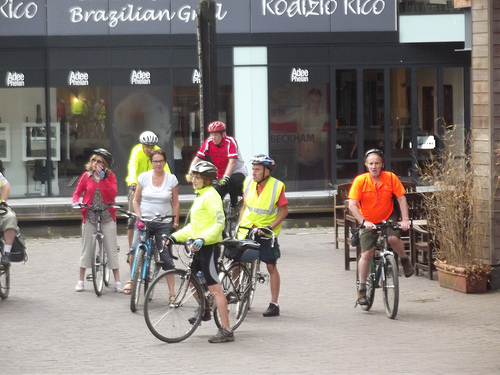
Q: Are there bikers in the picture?
A: Yes, there is a biker.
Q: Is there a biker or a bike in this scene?
A: Yes, there is a biker.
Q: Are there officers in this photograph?
A: No, there are no officers.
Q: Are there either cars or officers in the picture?
A: No, there are no officers or cars.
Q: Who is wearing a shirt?
A: The biker is wearing a shirt.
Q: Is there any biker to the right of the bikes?
A: Yes, there is a biker to the right of the bikes.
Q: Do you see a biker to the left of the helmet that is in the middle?
A: Yes, there is a biker to the left of the helmet.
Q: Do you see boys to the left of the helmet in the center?
A: No, there is a biker to the left of the helmet.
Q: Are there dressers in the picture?
A: No, there are no dressers.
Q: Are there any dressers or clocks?
A: No, there are no dressers or clocks.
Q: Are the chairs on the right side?
A: Yes, the chairs are on the right of the image.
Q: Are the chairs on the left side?
A: No, the chairs are on the right of the image.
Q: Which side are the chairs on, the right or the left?
A: The chairs are on the right of the image.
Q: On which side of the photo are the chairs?
A: The chairs are on the right of the image.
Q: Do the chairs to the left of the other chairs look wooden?
A: Yes, the chairs are wooden.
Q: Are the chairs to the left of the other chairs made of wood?
A: Yes, the chairs are made of wood.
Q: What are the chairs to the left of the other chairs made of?
A: The chairs are made of wood.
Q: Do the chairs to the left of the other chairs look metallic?
A: No, the chairs are wooden.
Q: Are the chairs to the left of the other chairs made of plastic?
A: No, the chairs are made of wood.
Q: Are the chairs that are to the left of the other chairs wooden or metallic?
A: The chairs are wooden.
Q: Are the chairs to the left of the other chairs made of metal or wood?
A: The chairs are made of wood.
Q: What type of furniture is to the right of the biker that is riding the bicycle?
A: The pieces of furniture are chairs.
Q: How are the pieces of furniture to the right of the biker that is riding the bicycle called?
A: The pieces of furniture are chairs.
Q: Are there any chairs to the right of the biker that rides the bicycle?
A: Yes, there are chairs to the right of the biker.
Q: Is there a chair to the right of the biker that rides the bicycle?
A: Yes, there are chairs to the right of the biker.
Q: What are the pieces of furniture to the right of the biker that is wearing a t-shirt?
A: The pieces of furniture are chairs.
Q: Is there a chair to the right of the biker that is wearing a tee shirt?
A: Yes, there are chairs to the right of the biker.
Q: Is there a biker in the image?
A: Yes, there is a biker.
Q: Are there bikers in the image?
A: Yes, there is a biker.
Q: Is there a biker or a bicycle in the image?
A: Yes, there is a biker.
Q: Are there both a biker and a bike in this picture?
A: Yes, there are both a biker and a bike.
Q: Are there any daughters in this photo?
A: No, there are no daughters.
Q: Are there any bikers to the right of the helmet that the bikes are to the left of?
A: Yes, there is a biker to the right of the helmet.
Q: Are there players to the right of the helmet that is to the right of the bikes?
A: No, there is a biker to the right of the helmet.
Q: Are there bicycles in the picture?
A: Yes, there are bicycles.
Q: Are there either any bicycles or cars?
A: Yes, there are bicycles.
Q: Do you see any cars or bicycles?
A: Yes, there are bicycles.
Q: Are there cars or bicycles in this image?
A: Yes, there are bicycles.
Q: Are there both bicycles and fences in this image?
A: No, there are bicycles but no fences.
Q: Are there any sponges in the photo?
A: No, there are no sponges.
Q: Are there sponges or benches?
A: No, there are no sponges or benches.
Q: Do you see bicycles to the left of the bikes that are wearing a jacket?
A: Yes, there are bicycles to the left of the bicycles.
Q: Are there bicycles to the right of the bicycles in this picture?
A: No, the bicycles are to the left of the bicycles.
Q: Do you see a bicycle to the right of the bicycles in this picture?
A: No, the bicycles are to the left of the bicycles.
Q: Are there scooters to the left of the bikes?
A: No, there are bicycles to the left of the bikes.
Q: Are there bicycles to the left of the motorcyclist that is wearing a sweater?
A: Yes, there are bicycles to the left of the motorcyclist.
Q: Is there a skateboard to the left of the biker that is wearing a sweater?
A: No, there are bicycles to the left of the biker.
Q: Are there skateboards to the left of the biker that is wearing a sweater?
A: No, there are bicycles to the left of the biker.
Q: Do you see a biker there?
A: Yes, there is a biker.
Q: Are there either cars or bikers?
A: Yes, there is a biker.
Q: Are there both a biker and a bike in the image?
A: Yes, there are both a biker and a bike.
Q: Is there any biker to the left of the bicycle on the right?
A: Yes, there is a biker to the left of the bicycle.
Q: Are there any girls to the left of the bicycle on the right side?
A: No, there is a biker to the left of the bicycle.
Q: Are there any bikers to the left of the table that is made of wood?
A: Yes, there is a biker to the left of the table.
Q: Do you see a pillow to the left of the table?
A: No, there is a biker to the left of the table.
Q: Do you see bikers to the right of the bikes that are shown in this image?
A: Yes, there is a biker to the right of the bikes.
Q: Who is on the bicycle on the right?
A: The motorcyclist is on the bicycle.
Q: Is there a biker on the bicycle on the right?
A: Yes, there is a biker on the bicycle.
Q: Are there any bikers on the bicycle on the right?
A: Yes, there is a biker on the bicycle.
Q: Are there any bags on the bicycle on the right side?
A: No, there is a biker on the bicycle.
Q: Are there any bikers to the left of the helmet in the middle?
A: Yes, there is a biker to the left of the helmet.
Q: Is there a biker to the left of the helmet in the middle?
A: Yes, there is a biker to the left of the helmet.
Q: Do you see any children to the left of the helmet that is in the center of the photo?
A: No, there is a biker to the left of the helmet.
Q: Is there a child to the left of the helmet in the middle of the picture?
A: No, there is a biker to the left of the helmet.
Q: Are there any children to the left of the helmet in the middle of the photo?
A: No, there is a biker to the left of the helmet.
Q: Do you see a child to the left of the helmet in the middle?
A: No, there is a biker to the left of the helmet.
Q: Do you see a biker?
A: Yes, there is a biker.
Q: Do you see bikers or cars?
A: Yes, there is a biker.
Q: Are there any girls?
A: No, there are no girls.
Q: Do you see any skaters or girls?
A: No, there are no girls or skaters.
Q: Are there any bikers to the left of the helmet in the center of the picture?
A: Yes, there is a biker to the left of the helmet.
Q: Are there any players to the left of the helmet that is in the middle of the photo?
A: No, there is a biker to the left of the helmet.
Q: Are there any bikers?
A: Yes, there is a biker.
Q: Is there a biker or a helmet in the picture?
A: Yes, there is a biker.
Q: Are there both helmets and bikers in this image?
A: Yes, there are both a biker and a helmet.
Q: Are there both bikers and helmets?
A: Yes, there are both a biker and a helmet.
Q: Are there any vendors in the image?
A: No, there are no vendors.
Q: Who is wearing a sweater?
A: The motorcyclist is wearing a sweater.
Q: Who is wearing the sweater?
A: The motorcyclist is wearing a sweater.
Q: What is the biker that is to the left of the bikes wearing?
A: The biker is wearing a sweater.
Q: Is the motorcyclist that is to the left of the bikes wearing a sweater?
A: Yes, the biker is wearing a sweater.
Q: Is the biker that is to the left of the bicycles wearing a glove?
A: No, the biker is wearing a sweater.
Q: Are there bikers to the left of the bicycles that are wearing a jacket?
A: Yes, there is a biker to the left of the bikes.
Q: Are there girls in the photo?
A: No, there are no girls.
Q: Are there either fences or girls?
A: No, there are no girls or fences.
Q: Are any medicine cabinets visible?
A: No, there are no medicine cabinets.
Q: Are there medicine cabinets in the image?
A: No, there are no medicine cabinets.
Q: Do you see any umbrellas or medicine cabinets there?
A: No, there are no medicine cabinets or umbrellas.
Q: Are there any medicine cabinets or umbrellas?
A: No, there are no medicine cabinets or umbrellas.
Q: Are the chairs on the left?
A: No, the chairs are on the right of the image.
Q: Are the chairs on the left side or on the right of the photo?
A: The chairs are on the right of the image.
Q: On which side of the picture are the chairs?
A: The chairs are on the right of the image.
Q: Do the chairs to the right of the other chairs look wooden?
A: Yes, the chairs are wooden.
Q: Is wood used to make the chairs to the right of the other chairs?
A: Yes, the chairs are made of wood.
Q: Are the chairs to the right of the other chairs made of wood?
A: Yes, the chairs are made of wood.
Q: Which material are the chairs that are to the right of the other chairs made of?
A: The chairs are made of wood.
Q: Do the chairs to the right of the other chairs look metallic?
A: No, the chairs are wooden.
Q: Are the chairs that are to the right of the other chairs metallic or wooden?
A: The chairs are wooden.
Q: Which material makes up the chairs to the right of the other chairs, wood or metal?
A: The chairs are made of wood.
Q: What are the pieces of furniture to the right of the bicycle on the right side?
A: The pieces of furniture are chairs.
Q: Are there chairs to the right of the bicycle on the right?
A: Yes, there are chairs to the right of the bicycle.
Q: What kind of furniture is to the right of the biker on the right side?
A: The pieces of furniture are chairs.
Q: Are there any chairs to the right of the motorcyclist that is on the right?
A: Yes, there are chairs to the right of the motorcyclist.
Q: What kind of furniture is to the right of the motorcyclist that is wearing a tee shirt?
A: The pieces of furniture are chairs.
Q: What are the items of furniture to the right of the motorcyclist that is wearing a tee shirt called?
A: The pieces of furniture are chairs.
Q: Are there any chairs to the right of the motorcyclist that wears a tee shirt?
A: Yes, there are chairs to the right of the motorcyclist.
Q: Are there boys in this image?
A: No, there are no boys.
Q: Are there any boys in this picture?
A: No, there are no boys.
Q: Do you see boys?
A: No, there are no boys.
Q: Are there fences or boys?
A: No, there are no boys or fences.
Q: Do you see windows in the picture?
A: Yes, there is a window.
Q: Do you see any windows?
A: Yes, there is a window.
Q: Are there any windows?
A: Yes, there is a window.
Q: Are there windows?
A: Yes, there is a window.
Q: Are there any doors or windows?
A: Yes, there is a window.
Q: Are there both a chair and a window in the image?
A: Yes, there are both a window and a chair.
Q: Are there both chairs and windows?
A: Yes, there are both a window and a chair.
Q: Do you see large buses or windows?
A: Yes, there is a large window.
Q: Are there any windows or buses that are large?
A: Yes, the window is large.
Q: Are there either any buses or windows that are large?
A: Yes, the window is large.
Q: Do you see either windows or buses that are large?
A: Yes, the window is large.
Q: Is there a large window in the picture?
A: Yes, there is a large window.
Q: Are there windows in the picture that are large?
A: Yes, there is a window that is large.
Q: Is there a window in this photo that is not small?
A: Yes, there is a large window.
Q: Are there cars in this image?
A: No, there are no cars.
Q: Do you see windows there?
A: Yes, there is a window.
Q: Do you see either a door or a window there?
A: Yes, there is a window.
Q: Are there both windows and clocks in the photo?
A: No, there is a window but no clocks.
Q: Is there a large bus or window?
A: Yes, there is a large window.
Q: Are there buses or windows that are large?
A: Yes, the window is large.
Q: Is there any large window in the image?
A: Yes, there is a large window.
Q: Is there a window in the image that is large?
A: Yes, there is a window that is large.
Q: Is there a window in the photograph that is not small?
A: Yes, there is a large window.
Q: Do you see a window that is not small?
A: Yes, there is a large window.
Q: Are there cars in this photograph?
A: No, there are no cars.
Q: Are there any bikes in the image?
A: Yes, there are bikes.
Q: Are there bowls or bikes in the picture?
A: Yes, there are bikes.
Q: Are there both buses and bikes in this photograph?
A: No, there are bikes but no buses.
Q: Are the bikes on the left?
A: Yes, the bikes are on the left of the image.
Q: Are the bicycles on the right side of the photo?
A: No, the bicycles are on the left of the image.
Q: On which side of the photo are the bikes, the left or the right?
A: The bikes are on the left of the image.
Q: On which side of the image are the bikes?
A: The bikes are on the left of the image.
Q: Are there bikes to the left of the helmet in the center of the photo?
A: Yes, there are bikes to the left of the helmet.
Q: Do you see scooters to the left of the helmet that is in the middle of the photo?
A: No, there are bikes to the left of the helmet.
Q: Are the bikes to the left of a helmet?
A: Yes, the bikes are to the left of a helmet.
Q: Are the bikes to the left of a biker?
A: Yes, the bikes are to the left of a biker.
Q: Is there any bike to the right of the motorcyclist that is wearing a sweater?
A: Yes, there are bikes to the right of the biker.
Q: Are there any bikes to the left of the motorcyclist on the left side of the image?
A: No, the bikes are to the right of the motorcyclist.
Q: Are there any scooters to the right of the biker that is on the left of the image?
A: No, there are bikes to the right of the motorcyclist.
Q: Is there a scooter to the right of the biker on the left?
A: No, there are bikes to the right of the motorcyclist.